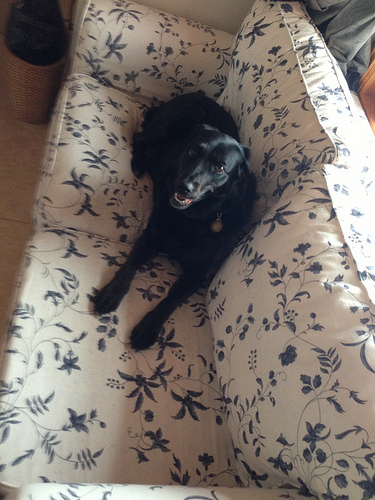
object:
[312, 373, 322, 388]
leaf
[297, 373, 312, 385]
leaf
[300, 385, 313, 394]
leaf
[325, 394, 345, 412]
leaf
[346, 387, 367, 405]
leaf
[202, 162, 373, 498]
material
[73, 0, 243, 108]
arm rest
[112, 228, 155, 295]
arm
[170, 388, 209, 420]
flower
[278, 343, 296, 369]
flowers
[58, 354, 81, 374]
flower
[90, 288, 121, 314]
paw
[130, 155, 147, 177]
paw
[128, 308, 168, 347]
black paws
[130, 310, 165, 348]
paws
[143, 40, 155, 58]
flower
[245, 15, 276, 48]
flower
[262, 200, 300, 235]
flower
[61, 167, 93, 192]
flower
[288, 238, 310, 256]
flower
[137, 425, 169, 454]
flower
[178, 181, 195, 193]
nose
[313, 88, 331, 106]
flower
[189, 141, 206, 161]
eyes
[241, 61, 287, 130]
print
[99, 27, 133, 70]
flower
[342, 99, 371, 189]
light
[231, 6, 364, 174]
cushion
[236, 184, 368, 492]
cushion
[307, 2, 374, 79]
curtain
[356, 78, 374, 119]
window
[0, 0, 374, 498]
sofa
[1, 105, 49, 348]
floor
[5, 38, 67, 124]
wicker basket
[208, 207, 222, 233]
collar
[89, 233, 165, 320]
leg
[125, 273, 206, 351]
leg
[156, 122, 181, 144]
fur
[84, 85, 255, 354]
dog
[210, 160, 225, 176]
eyes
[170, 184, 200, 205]
mouth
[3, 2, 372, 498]
couch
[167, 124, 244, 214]
head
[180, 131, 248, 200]
light